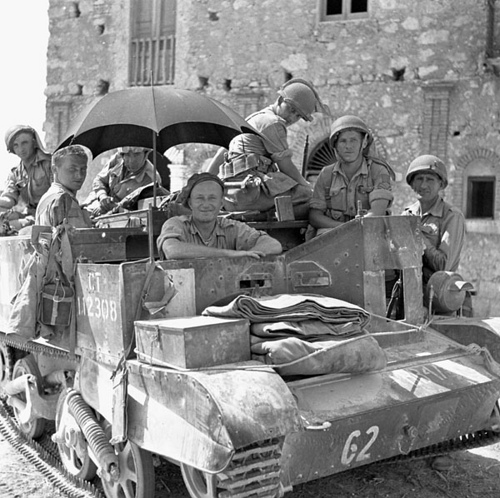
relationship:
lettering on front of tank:
[342, 425, 380, 465] [1, 202, 497, 497]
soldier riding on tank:
[308, 117, 392, 230] [1, 202, 497, 497]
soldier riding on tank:
[155, 175, 283, 258] [1, 202, 497, 497]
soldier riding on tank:
[402, 155, 465, 272] [1, 202, 497, 497]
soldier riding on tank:
[36, 146, 95, 228] [1, 202, 497, 497]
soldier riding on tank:
[223, 85, 315, 216] [1, 202, 497, 497]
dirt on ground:
[288, 448, 499, 497] [1, 436, 499, 497]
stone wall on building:
[46, 3, 499, 321] [49, 1, 498, 322]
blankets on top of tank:
[202, 295, 384, 372] [1, 202, 497, 497]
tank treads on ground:
[1, 333, 277, 497] [1, 436, 499, 497]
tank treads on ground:
[369, 409, 499, 468] [1, 436, 499, 497]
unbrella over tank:
[53, 86, 269, 160] [1, 202, 497, 497]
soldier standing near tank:
[402, 155, 465, 272] [1, 202, 497, 497]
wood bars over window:
[128, 36, 174, 85] [131, 0, 175, 82]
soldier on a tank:
[1, 130, 54, 234] [1, 202, 497, 497]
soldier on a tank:
[36, 146, 95, 228] [1, 202, 497, 497]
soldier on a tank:
[155, 175, 283, 258] [1, 202, 497, 497]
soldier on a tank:
[223, 85, 315, 216] [1, 202, 497, 497]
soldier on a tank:
[308, 117, 392, 230] [1, 202, 497, 497]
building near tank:
[49, 1, 498, 322] [1, 202, 497, 497]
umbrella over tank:
[53, 86, 269, 160] [1, 202, 497, 497]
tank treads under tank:
[1, 333, 277, 497] [1, 202, 497, 497]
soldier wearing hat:
[155, 175, 283, 258] [177, 173, 224, 206]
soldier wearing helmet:
[402, 155, 465, 272] [406, 155, 448, 187]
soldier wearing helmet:
[308, 117, 392, 230] [326, 116, 374, 147]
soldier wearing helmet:
[223, 85, 315, 216] [275, 83, 314, 121]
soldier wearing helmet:
[1, 130, 54, 234] [7, 127, 35, 152]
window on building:
[131, 0, 175, 82] [49, 1, 498, 322]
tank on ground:
[1, 202, 497, 497] [1, 436, 499, 497]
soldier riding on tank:
[1, 130, 54, 234] [1, 202, 497, 497]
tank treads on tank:
[1, 333, 277, 497] [1, 202, 497, 497]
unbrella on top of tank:
[53, 86, 269, 160] [1, 202, 497, 497]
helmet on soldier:
[7, 127, 35, 152] [1, 130, 54, 234]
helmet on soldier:
[275, 83, 314, 121] [223, 85, 315, 216]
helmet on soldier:
[326, 116, 374, 147] [308, 117, 392, 230]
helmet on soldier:
[406, 155, 448, 187] [402, 155, 465, 272]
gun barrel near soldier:
[387, 280, 402, 314] [402, 155, 465, 272]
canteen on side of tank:
[42, 277, 72, 327] [1, 202, 497, 497]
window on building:
[468, 177, 493, 217] [49, 1, 498, 322]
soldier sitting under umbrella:
[155, 175, 283, 258] [53, 86, 269, 160]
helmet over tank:
[275, 83, 314, 121] [1, 202, 497, 497]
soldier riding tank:
[36, 146, 95, 228] [1, 202, 497, 497]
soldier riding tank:
[155, 175, 283, 258] [1, 202, 497, 497]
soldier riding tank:
[223, 85, 315, 216] [1, 202, 497, 497]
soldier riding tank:
[308, 117, 392, 230] [1, 202, 497, 497]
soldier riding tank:
[402, 155, 465, 272] [1, 202, 497, 497]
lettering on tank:
[76, 273, 118, 322] [1, 202, 497, 497]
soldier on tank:
[402, 155, 465, 272] [1, 202, 497, 497]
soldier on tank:
[308, 117, 392, 230] [1, 202, 497, 497]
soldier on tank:
[223, 85, 315, 216] [1, 202, 497, 497]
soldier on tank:
[155, 175, 283, 258] [1, 202, 497, 497]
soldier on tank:
[36, 146, 95, 228] [1, 202, 497, 497]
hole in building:
[390, 68, 408, 82] [49, 1, 498, 322]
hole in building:
[221, 77, 233, 91] [49, 1, 498, 322]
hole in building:
[199, 77, 210, 88] [49, 1, 498, 322]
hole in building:
[96, 81, 109, 94] [49, 1, 498, 322]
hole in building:
[208, 10, 221, 21] [49, 1, 498, 322]